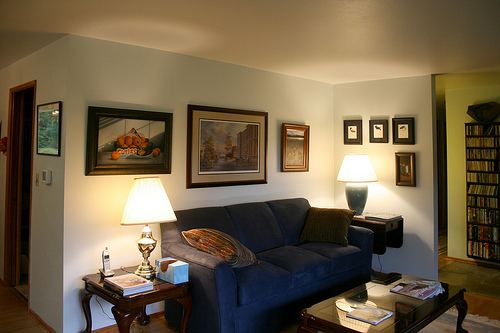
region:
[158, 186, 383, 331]
blue couch in the living room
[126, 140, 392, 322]
two lamps next to the couch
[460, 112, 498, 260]
bookshelf in the hallway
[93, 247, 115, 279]
white phone on the table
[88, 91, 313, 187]
three paintings above the couch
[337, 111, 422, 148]
three similar black and white pictures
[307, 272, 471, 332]
coffee table with a glass top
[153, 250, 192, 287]
tissue box on the table end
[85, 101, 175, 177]
painting of orange oranges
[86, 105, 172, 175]
The painting is hanging on the wall.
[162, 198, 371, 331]
The sofa is near to the lamp.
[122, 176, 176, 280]
The lamp is on the table.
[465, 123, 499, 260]
The shelf with books is near to the living room.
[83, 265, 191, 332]
The table has on it a telephone, a lamp and a book.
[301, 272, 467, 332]
The table is on the center of the living room.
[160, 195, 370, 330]
The sofa has two pillows.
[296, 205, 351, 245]
The pillow is on the sofa.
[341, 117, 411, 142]
This is a group of paintings.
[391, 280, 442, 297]
There a lot of magazines on the table.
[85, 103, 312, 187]
framed painting on a white wall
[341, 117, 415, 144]
framed cards on the wall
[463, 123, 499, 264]
a black bookshelf on the wall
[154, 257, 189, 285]
a box of tissue on a table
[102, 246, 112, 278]
a landline phone on a table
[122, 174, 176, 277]
a white lampshade over a silver base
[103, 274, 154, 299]
a hardcover book on a table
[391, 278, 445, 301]
a newspaper on a table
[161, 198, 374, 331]
a blue couch in the living room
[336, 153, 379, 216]
a white lampshade over a blue base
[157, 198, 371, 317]
a blue couch in a living room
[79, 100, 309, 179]
pictures in a living room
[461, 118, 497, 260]
bookshelf in a living room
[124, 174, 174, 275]
lamp in a living oom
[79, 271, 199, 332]
end table in a living room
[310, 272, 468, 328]
coffee table in a living room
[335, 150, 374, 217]
lamp in a living room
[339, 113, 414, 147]
pictures in a living room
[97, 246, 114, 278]
telephone in a living room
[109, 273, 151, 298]
book in a living room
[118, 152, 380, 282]
Two lamps on tables.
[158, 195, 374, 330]
A couch against a wall.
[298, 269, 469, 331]
A coffee table on a rug.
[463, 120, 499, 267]
A shelf full of books.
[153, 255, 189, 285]
A box of kleenex.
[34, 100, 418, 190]
Pictures on the wall.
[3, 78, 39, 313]
An open door way.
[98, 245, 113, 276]
A phone on a table.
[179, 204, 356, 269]
Pillows on a couch.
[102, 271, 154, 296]
A book on a table.